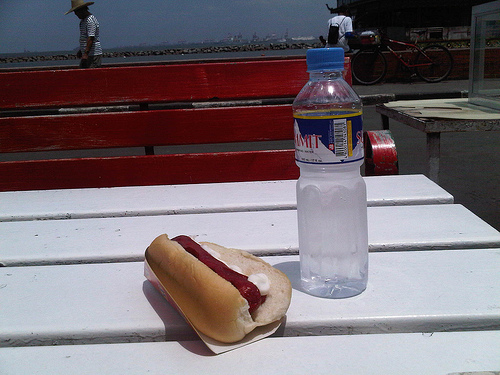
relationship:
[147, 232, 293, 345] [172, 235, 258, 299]
hot dog with ketchup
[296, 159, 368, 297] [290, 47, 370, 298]
water in a bottle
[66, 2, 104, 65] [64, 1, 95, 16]
man with a cowboy hat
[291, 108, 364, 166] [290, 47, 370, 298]
lable on bottle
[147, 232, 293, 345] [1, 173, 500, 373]
hot dog on a table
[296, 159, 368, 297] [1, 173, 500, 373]
water on a table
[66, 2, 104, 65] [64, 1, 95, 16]
man in a cowboy hat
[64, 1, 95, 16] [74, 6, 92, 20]
cowboy hat on h head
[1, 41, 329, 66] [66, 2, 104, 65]
seawall behind man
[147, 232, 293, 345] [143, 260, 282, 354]
hot dog on a paper container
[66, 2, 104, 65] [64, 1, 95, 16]
man wearing a cowboy hat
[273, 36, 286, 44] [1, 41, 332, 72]
ship on water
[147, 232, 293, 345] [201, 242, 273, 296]
hot dog with mayo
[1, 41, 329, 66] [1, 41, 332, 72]
seawall divides water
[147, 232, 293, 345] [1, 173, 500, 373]
hot dog sitting on a table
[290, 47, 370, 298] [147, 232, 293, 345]
bottle near hot dog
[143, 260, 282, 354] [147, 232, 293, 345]
paper container under hot dog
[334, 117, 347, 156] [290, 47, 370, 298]
barcode on bottle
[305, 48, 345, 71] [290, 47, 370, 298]
cap on bottle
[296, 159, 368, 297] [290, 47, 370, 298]
water in bottle